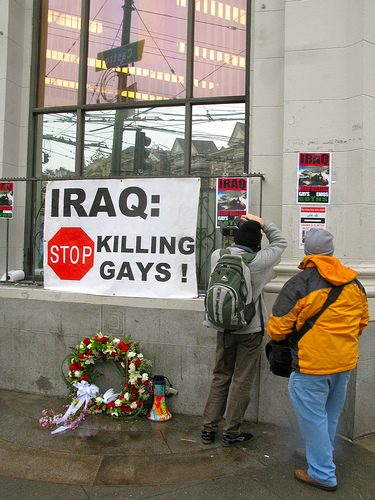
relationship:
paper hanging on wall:
[297, 151, 331, 203] [251, 1, 375, 319]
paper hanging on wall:
[299, 206, 327, 249] [251, 1, 375, 319]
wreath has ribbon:
[69, 334, 151, 418] [40, 381, 116, 434]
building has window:
[1, 1, 375, 441] [28, 0, 248, 288]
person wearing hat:
[266, 229, 369, 491] [305, 229, 334, 258]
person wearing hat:
[203, 214, 286, 445] [236, 220, 261, 250]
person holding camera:
[203, 214, 286, 445] [220, 219, 246, 235]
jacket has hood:
[266, 254, 369, 375] [298, 255, 358, 286]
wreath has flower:
[69, 334, 151, 418] [83, 338, 90, 345]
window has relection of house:
[28, 0, 248, 288] [41, 102, 245, 189]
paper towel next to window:
[2, 270, 24, 282] [28, 0, 248, 288]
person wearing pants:
[266, 229, 369, 491] [289, 373, 350, 487]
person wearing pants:
[203, 214, 286, 445] [204, 331, 263, 434]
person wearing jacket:
[266, 229, 369, 491] [266, 254, 369, 375]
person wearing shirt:
[203, 214, 286, 445] [204, 221, 288, 335]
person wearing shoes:
[266, 229, 369, 491] [295, 448, 336, 489]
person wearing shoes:
[203, 214, 286, 445] [202, 431, 252, 445]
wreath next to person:
[69, 334, 151, 418] [203, 214, 286, 445]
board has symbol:
[44, 177, 202, 298] [48, 227, 95, 280]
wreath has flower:
[69, 334, 151, 418] [134, 359, 142, 367]